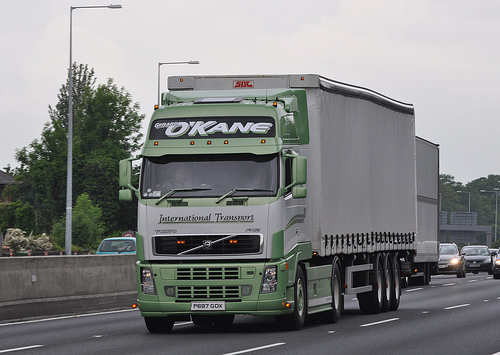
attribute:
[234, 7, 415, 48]
sky — overcast, white, gray, dark, cloudy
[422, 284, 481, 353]
road — black, white, paved, gray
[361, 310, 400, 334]
line — white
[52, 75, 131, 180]
tree — tall, green, large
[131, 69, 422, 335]
truck — white, green, gray, silver, big, huge, close, moving, visable, massive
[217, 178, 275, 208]
wiper — windshield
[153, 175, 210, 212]
wiper — windshield